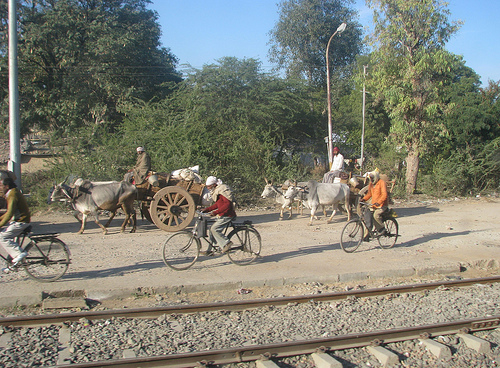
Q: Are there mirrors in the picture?
A: No, there are no mirrors.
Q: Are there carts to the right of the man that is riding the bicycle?
A: Yes, there is a cart to the right of the man.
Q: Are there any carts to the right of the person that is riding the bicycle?
A: Yes, there is a cart to the right of the man.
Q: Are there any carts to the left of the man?
A: No, the cart is to the right of the man.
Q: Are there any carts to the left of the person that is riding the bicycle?
A: No, the cart is to the right of the man.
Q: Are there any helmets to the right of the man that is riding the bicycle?
A: No, there is a cart to the right of the man.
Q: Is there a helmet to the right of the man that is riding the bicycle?
A: No, there is a cart to the right of the man.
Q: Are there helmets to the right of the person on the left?
A: No, there is a cart to the right of the man.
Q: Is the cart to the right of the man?
A: Yes, the cart is to the right of the man.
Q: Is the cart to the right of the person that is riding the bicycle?
A: Yes, the cart is to the right of the man.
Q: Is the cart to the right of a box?
A: No, the cart is to the right of the man.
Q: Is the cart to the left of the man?
A: No, the cart is to the right of the man.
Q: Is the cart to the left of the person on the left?
A: No, the cart is to the right of the man.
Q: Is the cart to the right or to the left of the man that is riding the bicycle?
A: The cart is to the right of the man.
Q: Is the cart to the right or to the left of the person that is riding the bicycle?
A: The cart is to the right of the man.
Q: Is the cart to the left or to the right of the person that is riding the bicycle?
A: The cart is to the right of the man.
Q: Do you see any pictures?
A: No, there are no pictures.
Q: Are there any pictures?
A: No, there are no pictures.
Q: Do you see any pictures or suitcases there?
A: No, there are no pictures or suitcases.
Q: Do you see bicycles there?
A: Yes, there is a bicycle.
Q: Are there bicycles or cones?
A: Yes, there is a bicycle.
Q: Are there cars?
A: No, there are no cars.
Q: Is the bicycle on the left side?
A: Yes, the bicycle is on the left of the image.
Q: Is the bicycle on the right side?
A: No, the bicycle is on the left of the image.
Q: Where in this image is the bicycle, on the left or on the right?
A: The bicycle is on the left of the image.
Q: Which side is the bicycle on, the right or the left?
A: The bicycle is on the left of the image.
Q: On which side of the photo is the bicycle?
A: The bicycle is on the left of the image.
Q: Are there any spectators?
A: No, there are no spectators.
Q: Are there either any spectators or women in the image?
A: No, there are no spectators or women.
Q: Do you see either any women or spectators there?
A: No, there are no spectators or women.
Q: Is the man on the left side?
A: Yes, the man is on the left of the image.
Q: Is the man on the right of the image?
A: No, the man is on the left of the image.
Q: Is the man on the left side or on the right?
A: The man is on the left of the image.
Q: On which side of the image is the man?
A: The man is on the left of the image.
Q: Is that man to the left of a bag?
A: No, the man is to the left of the cart.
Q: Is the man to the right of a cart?
A: No, the man is to the left of a cart.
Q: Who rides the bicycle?
A: The man rides the bicycle.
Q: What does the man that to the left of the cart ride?
A: The man rides the bicycle.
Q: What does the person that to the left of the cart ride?
A: The man rides the bicycle.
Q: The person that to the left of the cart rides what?
A: The man rides the bicycle.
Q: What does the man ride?
A: The man rides the bicycle.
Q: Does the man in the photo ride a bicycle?
A: Yes, the man rides a bicycle.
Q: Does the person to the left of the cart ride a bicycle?
A: Yes, the man rides a bicycle.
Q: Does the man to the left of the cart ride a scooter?
A: No, the man rides a bicycle.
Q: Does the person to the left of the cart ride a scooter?
A: No, the man rides a bicycle.